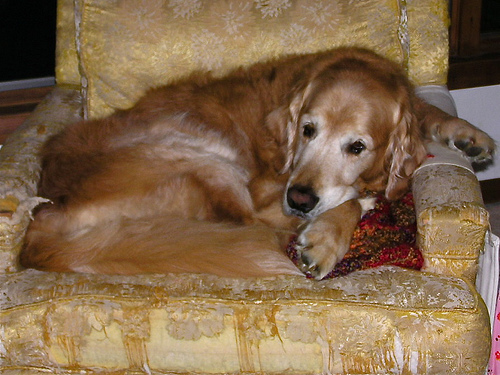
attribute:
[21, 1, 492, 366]
chair — arm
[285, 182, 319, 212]
nose — brown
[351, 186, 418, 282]
bag — pink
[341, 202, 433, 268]
blanket — red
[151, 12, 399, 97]
fabric — flowered, upholstery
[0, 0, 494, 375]
cushon — chair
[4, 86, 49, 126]
table — wooden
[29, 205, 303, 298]
tail — fluffy